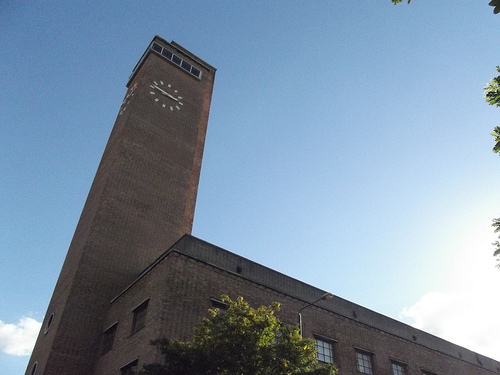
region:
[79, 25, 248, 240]
A tall clock tower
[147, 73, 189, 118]
A clock at 3:50 PM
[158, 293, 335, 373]
A leafy treetop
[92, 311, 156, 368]
Windows on the side of a building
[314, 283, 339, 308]
A lamp attached to a building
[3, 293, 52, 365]
A white cloud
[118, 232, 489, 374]
A brick building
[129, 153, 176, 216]
red bricks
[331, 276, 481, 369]
the top of a brick building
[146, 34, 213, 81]
A thin rectangular window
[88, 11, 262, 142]
a tall clock tower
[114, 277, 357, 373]
the green tree on the side of the building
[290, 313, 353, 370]
glass windows on the side of the building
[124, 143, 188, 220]
the brick wall of the tower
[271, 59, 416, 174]
clear blue sky in the background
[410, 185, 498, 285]
the sun shining from behind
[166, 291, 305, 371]
green leaves on the tree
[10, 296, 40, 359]
a single white cloud in the background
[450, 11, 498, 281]
green leaves on the edge of the picture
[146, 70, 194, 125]
white hands of the clock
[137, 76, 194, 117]
a clock on the side of a building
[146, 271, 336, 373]
the top of a tree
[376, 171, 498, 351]
the sun in the corner of the building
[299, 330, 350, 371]
a window in the building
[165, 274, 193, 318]
a brick wall on the building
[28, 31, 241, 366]
a clock tower with the clock on it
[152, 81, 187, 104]
the hands of the clock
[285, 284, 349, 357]
a lamp post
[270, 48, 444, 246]
a clear blue sky above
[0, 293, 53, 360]
a white cloud in the sky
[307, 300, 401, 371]
A building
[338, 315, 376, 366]
A building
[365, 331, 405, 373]
A building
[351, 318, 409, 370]
A building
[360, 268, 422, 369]
A building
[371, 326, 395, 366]
A building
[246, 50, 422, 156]
Sky is blue and clear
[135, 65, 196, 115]
The white clock is at the top of the tower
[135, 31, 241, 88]
windows at the top of the tower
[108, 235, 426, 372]
The building is made of bricks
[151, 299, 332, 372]
The tree is leafy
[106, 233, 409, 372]
The building has small windows.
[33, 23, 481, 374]
The building is large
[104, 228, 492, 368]
The roof is brown.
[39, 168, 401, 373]
The building is brown.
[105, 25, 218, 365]
The tower is narrow